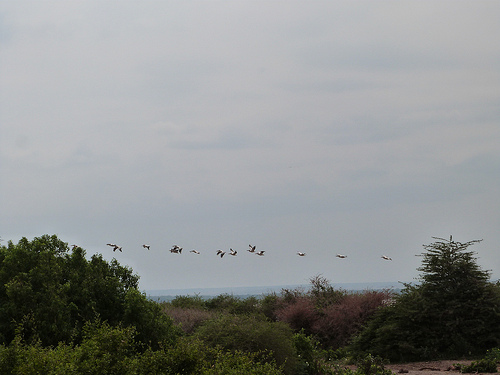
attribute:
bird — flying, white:
[381, 253, 393, 261]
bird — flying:
[336, 252, 347, 258]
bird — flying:
[296, 250, 306, 257]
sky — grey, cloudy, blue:
[0, 0, 500, 303]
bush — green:
[345, 234, 499, 362]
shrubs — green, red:
[157, 275, 400, 340]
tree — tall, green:
[0, 233, 139, 356]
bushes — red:
[271, 288, 389, 343]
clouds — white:
[0, 0, 499, 229]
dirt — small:
[369, 358, 498, 374]